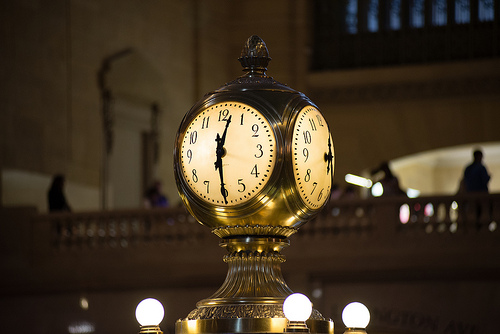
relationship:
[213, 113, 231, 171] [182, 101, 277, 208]
hand on clock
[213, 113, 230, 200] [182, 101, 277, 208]
hand on clock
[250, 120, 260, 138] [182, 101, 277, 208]
number on clock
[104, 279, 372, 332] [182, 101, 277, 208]
lights below clock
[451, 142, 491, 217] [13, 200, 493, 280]
person on balcony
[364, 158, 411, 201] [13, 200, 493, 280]
person on balcony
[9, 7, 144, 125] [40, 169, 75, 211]
wall near person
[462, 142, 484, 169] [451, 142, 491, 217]
head of a person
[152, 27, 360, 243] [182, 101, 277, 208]
piece with clock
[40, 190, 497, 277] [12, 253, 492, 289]
barrier on floor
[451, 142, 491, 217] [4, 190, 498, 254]
person leaning on fence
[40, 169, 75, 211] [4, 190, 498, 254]
person leaning on fence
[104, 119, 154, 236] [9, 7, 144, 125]
door in wall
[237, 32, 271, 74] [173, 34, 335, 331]
brass piece on clock